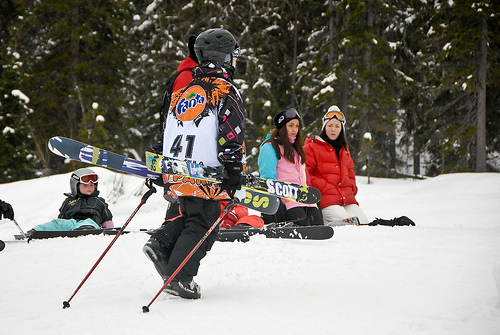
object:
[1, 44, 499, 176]
branches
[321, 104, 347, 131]
hat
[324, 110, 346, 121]
goggles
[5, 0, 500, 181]
trees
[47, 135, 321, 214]
skis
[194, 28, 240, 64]
helmet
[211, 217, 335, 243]
ski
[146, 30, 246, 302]
child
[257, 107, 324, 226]
child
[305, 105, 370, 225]
child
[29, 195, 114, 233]
ski outfit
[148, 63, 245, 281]
ski outfit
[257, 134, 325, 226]
ski outfit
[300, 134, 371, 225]
ski outfit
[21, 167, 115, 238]
boy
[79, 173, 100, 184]
goggles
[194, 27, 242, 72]
head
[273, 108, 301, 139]
head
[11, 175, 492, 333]
snow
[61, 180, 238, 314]
poles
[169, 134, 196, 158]
number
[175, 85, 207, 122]
logos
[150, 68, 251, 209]
jacket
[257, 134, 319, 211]
jacket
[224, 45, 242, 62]
goggles